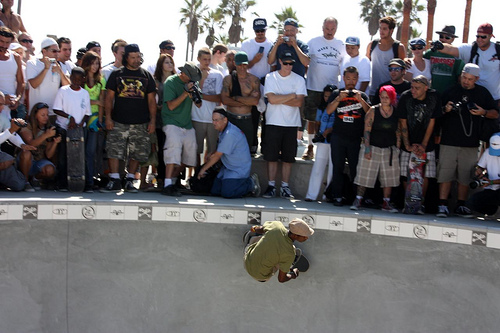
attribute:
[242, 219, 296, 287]
shirt — green 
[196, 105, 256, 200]
man —  kneeling down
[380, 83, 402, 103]
hair — pink 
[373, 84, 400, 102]
hair — pink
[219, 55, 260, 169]
man — shirtless